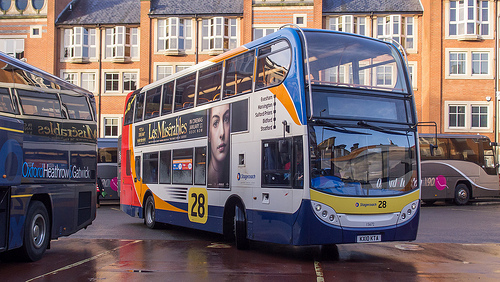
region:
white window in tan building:
[443, 0, 498, 40]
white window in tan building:
[443, 40, 492, 78]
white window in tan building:
[57, 12, 127, 63]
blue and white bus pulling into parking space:
[119, 11, 421, 248]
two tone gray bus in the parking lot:
[413, 131, 498, 207]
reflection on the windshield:
[308, 130, 413, 189]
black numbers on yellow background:
[185, 189, 205, 220]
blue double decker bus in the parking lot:
[3, 49, 98, 254]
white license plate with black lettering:
[353, 234, 385, 243]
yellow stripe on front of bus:
[312, 192, 418, 214]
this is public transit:
[131, 47, 259, 209]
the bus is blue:
[192, 65, 497, 262]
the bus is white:
[107, 71, 384, 272]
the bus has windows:
[148, 81, 248, 139]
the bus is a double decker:
[162, 53, 344, 257]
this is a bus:
[112, 18, 423, 258]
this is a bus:
[1, 45, 104, 262]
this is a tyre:
[215, 189, 260, 249]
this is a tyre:
[135, 183, 162, 228]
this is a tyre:
[17, 188, 58, 258]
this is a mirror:
[295, 24, 418, 126]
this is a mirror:
[248, 36, 294, 88]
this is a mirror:
[190, 58, 225, 103]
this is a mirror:
[112, 23, 125, 60]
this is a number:
[185, 178, 216, 225]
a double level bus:
[115, 20, 431, 252]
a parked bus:
[0, 46, 102, 257]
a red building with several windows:
[0, 3, 496, 55]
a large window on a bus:
[289, 23, 409, 87]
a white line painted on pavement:
[24, 235, 135, 280]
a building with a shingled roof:
[51, 5, 143, 36]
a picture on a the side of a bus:
[197, 92, 235, 197]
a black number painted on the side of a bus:
[183, 180, 212, 227]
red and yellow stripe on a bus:
[123, 122, 174, 224]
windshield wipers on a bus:
[311, 121, 418, 136]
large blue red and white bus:
[110, 22, 425, 257]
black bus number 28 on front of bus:
[373, 195, 394, 212]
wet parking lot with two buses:
[25, 194, 485, 280]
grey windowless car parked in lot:
[420, 155, 498, 203]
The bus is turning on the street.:
[96, 32, 442, 259]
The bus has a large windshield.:
[307, 121, 432, 198]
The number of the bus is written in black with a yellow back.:
[186, 186, 211, 223]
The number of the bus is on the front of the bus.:
[376, 192, 391, 209]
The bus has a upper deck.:
[117, 34, 412, 132]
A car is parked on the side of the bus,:
[418, 150, 495, 207]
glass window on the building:
[446, 103, 464, 123]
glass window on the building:
[467, 102, 487, 125]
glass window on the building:
[448, 51, 464, 72]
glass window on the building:
[471, 52, 486, 73]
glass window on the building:
[455, 0, 463, 35]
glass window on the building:
[466, 0, 476, 35]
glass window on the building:
[480, 0, 490, 33]